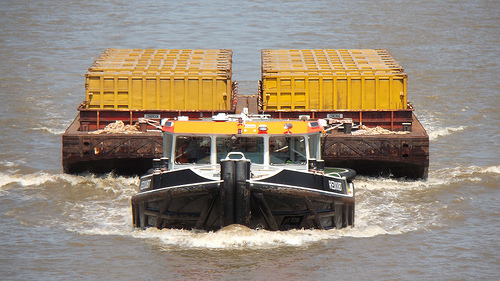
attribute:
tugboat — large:
[61, 44, 428, 235]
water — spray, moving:
[3, 0, 500, 281]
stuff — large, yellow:
[84, 38, 416, 123]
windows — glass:
[172, 131, 308, 164]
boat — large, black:
[129, 117, 359, 229]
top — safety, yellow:
[163, 118, 324, 136]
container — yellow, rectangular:
[84, 40, 240, 108]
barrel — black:
[340, 118, 354, 134]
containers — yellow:
[260, 44, 400, 118]